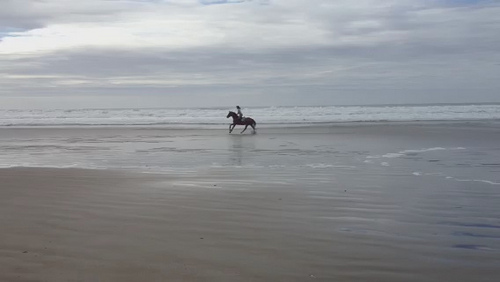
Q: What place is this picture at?
A: It is at the beach.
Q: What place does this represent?
A: It represents the beach.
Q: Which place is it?
A: It is a beach.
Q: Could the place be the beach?
A: Yes, it is the beach.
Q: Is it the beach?
A: Yes, it is the beach.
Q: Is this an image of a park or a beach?
A: It is showing a beach.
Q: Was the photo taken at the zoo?
A: No, the picture was taken in the beach.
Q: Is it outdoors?
A: Yes, it is outdoors.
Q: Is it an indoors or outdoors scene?
A: It is outdoors.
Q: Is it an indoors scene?
A: No, it is outdoors.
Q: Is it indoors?
A: No, it is outdoors.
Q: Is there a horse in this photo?
A: Yes, there is a horse.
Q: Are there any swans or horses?
A: Yes, there is a horse.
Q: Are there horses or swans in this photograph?
A: Yes, there is a horse.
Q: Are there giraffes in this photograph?
A: No, there are no giraffes.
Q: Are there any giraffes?
A: No, there are no giraffes.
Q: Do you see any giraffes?
A: No, there are no giraffes.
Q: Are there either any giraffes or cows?
A: No, there are no giraffes or cows.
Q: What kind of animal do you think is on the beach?
A: The animal is a horse.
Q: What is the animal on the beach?
A: The animal is a horse.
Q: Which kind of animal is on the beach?
A: The animal is a horse.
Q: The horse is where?
A: The horse is on the beach.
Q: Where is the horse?
A: The horse is on the beach.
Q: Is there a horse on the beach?
A: Yes, there is a horse on the beach.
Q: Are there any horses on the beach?
A: Yes, there is a horse on the beach.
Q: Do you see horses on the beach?
A: Yes, there is a horse on the beach.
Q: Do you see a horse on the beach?
A: Yes, there is a horse on the beach.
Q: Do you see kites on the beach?
A: No, there is a horse on the beach.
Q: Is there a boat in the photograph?
A: No, there are no boats.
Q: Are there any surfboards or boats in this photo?
A: No, there are no boats or surfboards.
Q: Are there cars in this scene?
A: No, there are no cars.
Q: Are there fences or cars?
A: No, there are no cars or fences.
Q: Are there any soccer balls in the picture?
A: No, there are no soccer balls.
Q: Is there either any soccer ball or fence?
A: No, there are no soccer balls or fences.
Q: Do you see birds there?
A: No, there are no birds.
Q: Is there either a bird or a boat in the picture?
A: No, there are no birds or boats.